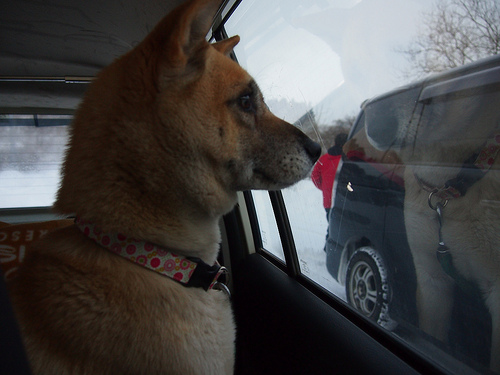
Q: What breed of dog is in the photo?
A: Shiba Inu.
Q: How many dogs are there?
A: One.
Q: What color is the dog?
A: Reddish brown.